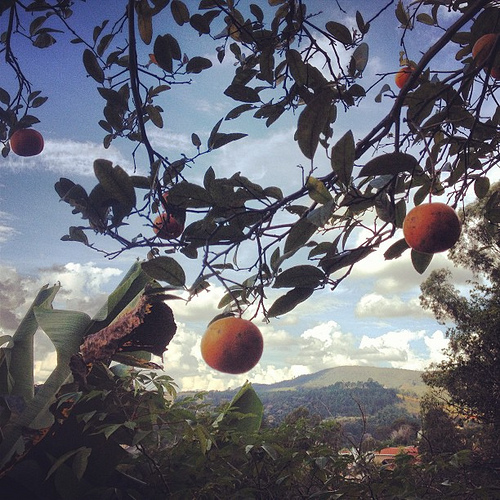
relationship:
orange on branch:
[395, 196, 462, 253] [408, 63, 477, 204]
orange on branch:
[391, 62, 422, 91] [396, 0, 425, 64]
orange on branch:
[191, 311, 270, 377] [201, 191, 273, 313]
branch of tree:
[408, 63, 477, 204] [2, 1, 500, 343]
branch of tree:
[396, 0, 425, 64] [2, 1, 500, 343]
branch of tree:
[201, 191, 273, 313] [2, 1, 500, 343]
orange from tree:
[395, 196, 462, 253] [2, 1, 500, 343]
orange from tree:
[391, 62, 422, 91] [2, 1, 500, 343]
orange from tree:
[191, 311, 270, 377] [2, 1, 500, 343]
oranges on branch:
[145, 183, 192, 243] [115, 6, 180, 218]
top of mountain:
[320, 360, 443, 376] [199, 359, 500, 446]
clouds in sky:
[284, 21, 376, 103] [2, 2, 499, 395]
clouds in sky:
[2, 262, 500, 394] [2, 2, 499, 395]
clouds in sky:
[340, 157, 500, 322] [2, 2, 499, 395]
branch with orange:
[408, 63, 477, 204] [395, 196, 462, 253]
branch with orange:
[396, 0, 425, 64] [391, 62, 422, 91]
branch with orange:
[201, 191, 273, 313] [191, 311, 270, 377]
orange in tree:
[395, 196, 462, 253] [2, 1, 500, 343]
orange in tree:
[391, 62, 422, 91] [2, 1, 500, 343]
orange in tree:
[191, 311, 270, 377] [2, 1, 500, 343]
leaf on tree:
[80, 278, 189, 383] [2, 1, 500, 343]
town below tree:
[253, 441, 500, 499] [2, 1, 500, 343]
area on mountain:
[179, 381, 422, 448] [199, 359, 500, 446]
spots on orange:
[237, 330, 247, 340] [191, 311, 270, 377]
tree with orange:
[2, 1, 500, 343] [395, 196, 462, 253]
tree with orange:
[2, 1, 500, 343] [391, 62, 422, 91]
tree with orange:
[2, 1, 500, 343] [191, 311, 270, 377]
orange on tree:
[395, 196, 462, 253] [2, 1, 500, 343]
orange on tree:
[391, 62, 422, 91] [2, 1, 500, 343]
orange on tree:
[191, 311, 270, 377] [2, 1, 500, 343]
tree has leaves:
[2, 1, 500, 343] [322, 129, 358, 189]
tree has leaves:
[2, 1, 500, 343] [92, 155, 143, 212]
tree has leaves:
[2, 1, 500, 343] [292, 85, 339, 158]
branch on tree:
[396, 0, 425, 64] [2, 1, 500, 343]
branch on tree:
[408, 63, 477, 204] [2, 1, 500, 343]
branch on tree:
[201, 191, 273, 313] [2, 1, 500, 343]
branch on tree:
[115, 6, 180, 218] [2, 1, 500, 343]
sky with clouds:
[2, 2, 499, 395] [284, 21, 376, 103]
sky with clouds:
[2, 2, 499, 395] [2, 262, 500, 394]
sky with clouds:
[2, 2, 499, 395] [340, 157, 500, 322]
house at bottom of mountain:
[370, 441, 428, 473] [199, 359, 500, 446]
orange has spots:
[395, 196, 462, 253] [237, 330, 247, 340]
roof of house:
[375, 441, 423, 457] [370, 441, 428, 473]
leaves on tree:
[322, 129, 358, 189] [2, 1, 500, 343]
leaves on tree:
[92, 155, 143, 212] [2, 1, 500, 343]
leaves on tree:
[292, 85, 339, 158] [2, 1, 500, 343]